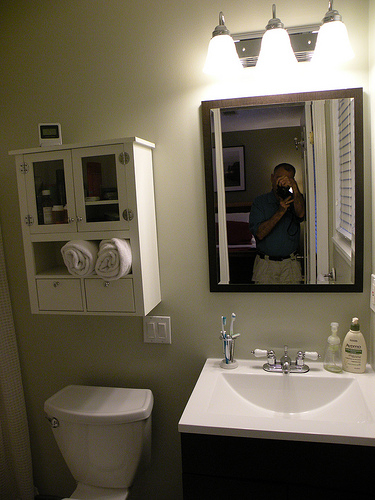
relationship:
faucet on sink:
[249, 342, 324, 375] [217, 346, 358, 416]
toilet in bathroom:
[35, 378, 158, 500] [7, 11, 374, 413]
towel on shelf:
[60, 238, 98, 275] [33, 261, 138, 285]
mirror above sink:
[208, 100, 356, 289] [159, 332, 374, 475]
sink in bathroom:
[170, 341, 373, 464] [3, 108, 372, 500]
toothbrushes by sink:
[215, 304, 243, 374] [170, 341, 373, 464]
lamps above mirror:
[193, 9, 364, 84] [208, 96, 356, 288]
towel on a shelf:
[57, 227, 135, 274] [20, 126, 159, 311]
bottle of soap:
[317, 319, 341, 374] [326, 363, 344, 373]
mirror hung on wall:
[208, 96, 356, 288] [2, 3, 365, 354]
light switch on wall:
[140, 313, 172, 345] [0, 0, 374, 499]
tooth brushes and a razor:
[219, 311, 235, 336] [230, 332, 240, 337]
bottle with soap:
[317, 319, 341, 374] [322, 314, 343, 374]